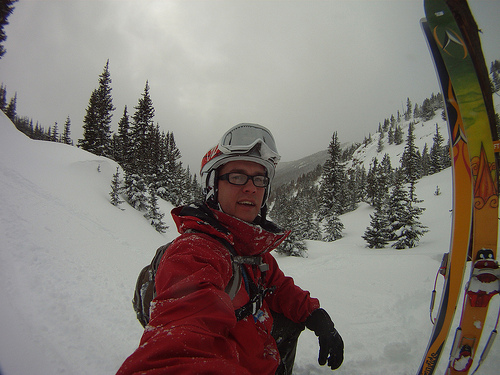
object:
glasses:
[218, 172, 271, 187]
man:
[118, 122, 343, 375]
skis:
[413, 11, 499, 375]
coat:
[128, 202, 321, 358]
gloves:
[305, 309, 345, 372]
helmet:
[196, 123, 281, 176]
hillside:
[0, 108, 129, 231]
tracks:
[351, 292, 393, 324]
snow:
[39, 193, 139, 346]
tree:
[110, 165, 171, 233]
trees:
[268, 92, 454, 259]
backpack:
[131, 237, 173, 329]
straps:
[224, 261, 273, 321]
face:
[216, 162, 271, 218]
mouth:
[236, 196, 257, 209]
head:
[205, 141, 277, 223]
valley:
[0, 59, 500, 290]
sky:
[0, 11, 500, 140]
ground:
[48, 208, 105, 305]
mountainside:
[326, 115, 459, 284]